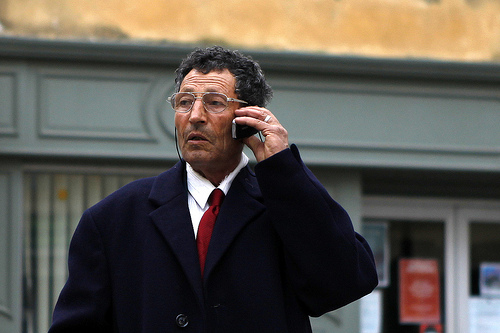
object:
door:
[379, 216, 447, 333]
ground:
[364, 184, 390, 224]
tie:
[194, 188, 224, 277]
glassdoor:
[447, 220, 469, 255]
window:
[366, 218, 443, 332]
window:
[471, 222, 499, 297]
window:
[31, 173, 176, 315]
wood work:
[0, 0, 499, 67]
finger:
[235, 105, 283, 130]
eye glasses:
[166, 91, 248, 113]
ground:
[411, 140, 447, 162]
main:
[45, 45, 381, 332]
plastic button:
[175, 311, 190, 328]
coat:
[46, 141, 381, 332]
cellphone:
[231, 116, 260, 139]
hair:
[171, 45, 276, 109]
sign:
[399, 258, 441, 325]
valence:
[20, 173, 138, 332]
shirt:
[183, 152, 250, 240]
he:
[47, 44, 381, 332]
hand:
[234, 105, 291, 166]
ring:
[264, 115, 272, 123]